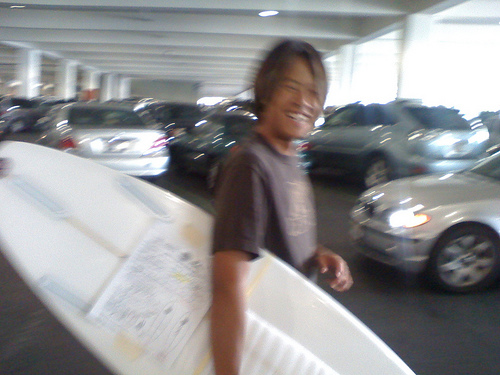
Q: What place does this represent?
A: It represents the garage.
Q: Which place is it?
A: It is a garage.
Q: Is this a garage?
A: Yes, it is a garage.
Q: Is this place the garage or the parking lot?
A: It is the garage.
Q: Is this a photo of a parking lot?
A: No, the picture is showing a garage.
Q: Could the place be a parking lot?
A: No, it is a garage.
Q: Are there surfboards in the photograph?
A: Yes, there is a surfboard.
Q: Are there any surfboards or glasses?
A: Yes, there is a surfboard.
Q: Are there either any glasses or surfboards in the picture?
A: Yes, there is a surfboard.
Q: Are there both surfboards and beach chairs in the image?
A: No, there is a surfboard but no beach chairs.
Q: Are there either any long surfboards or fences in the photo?
A: Yes, there is a long surfboard.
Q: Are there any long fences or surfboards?
A: Yes, there is a long surfboard.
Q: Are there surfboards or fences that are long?
A: Yes, the surfboard is long.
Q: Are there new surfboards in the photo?
A: Yes, there is a new surfboard.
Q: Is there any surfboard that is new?
A: Yes, there is a surfboard that is new.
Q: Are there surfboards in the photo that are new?
A: Yes, there is a surfboard that is new.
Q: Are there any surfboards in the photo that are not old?
A: Yes, there is an new surfboard.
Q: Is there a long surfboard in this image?
A: Yes, there is a long surfboard.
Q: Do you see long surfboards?
A: Yes, there is a long surfboard.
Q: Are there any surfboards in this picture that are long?
A: Yes, there is a surfboard that is long.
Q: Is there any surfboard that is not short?
A: Yes, there is a long surfboard.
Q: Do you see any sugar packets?
A: No, there are no sugar packets.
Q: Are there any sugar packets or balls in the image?
A: No, there are no sugar packets or balls.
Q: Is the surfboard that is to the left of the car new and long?
A: Yes, the surfboard is new and long.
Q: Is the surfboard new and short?
A: No, the surfboard is new but long.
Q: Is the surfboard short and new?
A: No, the surfboard is new but long.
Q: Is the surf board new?
A: Yes, the surf board is new.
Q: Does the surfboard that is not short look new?
A: Yes, the surfboard is new.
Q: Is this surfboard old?
A: No, the surfboard is new.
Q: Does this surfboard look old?
A: No, the surfboard is new.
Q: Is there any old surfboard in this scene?
A: No, there is a surfboard but it is new.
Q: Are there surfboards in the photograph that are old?
A: No, there is a surfboard but it is new.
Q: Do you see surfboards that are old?
A: No, there is a surfboard but it is new.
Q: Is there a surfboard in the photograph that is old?
A: No, there is a surfboard but it is new.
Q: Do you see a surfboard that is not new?
A: No, there is a surfboard but it is new.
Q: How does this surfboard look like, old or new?
A: The surfboard is new.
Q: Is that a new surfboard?
A: Yes, that is a new surfboard.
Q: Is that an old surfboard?
A: No, that is a new surfboard.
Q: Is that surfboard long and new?
A: Yes, the surfboard is long and new.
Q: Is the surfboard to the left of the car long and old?
A: No, the surfboard is long but new.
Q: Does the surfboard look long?
A: Yes, the surfboard is long.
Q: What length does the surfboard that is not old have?
A: The surfboard has long length.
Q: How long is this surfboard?
A: The surfboard is long.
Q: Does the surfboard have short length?
A: No, the surfboard is long.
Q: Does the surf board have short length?
A: No, the surf board is long.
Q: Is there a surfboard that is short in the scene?
A: No, there is a surfboard but it is long.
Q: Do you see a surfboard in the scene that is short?
A: No, there is a surfboard but it is long.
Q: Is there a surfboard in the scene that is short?
A: No, there is a surfboard but it is long.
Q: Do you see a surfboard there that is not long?
A: No, there is a surfboard but it is long.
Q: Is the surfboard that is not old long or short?
A: The surf board is long.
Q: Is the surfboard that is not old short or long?
A: The surf board is long.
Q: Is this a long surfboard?
A: Yes, this is a long surfboard.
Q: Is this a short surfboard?
A: No, this is a long surfboard.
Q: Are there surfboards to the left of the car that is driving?
A: Yes, there is a surfboard to the left of the car.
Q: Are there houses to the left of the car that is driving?
A: No, there is a surfboard to the left of the car.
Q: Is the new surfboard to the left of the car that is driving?
A: Yes, the surfboard is to the left of the car.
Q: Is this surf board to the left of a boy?
A: No, the surf board is to the left of the car.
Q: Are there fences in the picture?
A: No, there are no fences.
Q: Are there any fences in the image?
A: No, there are no fences.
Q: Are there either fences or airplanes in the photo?
A: No, there are no fences or airplanes.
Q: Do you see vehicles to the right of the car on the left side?
A: Yes, there is a vehicle to the right of the car.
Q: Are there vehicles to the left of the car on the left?
A: No, the vehicle is to the right of the car.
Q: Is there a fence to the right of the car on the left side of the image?
A: No, there is a vehicle to the right of the car.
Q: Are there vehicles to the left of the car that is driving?
A: Yes, there is a vehicle to the left of the car.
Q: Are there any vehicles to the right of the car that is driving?
A: No, the vehicle is to the left of the car.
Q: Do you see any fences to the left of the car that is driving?
A: No, there is a vehicle to the left of the car.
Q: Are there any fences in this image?
A: No, there are no fences.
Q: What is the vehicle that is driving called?
A: The vehicle is a car.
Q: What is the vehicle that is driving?
A: The vehicle is a car.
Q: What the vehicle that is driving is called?
A: The vehicle is a car.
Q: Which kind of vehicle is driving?
A: The vehicle is a car.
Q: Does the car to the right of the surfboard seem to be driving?
A: Yes, the car is driving.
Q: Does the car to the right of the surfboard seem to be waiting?
A: No, the car is driving.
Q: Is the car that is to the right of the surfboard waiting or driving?
A: The car is driving.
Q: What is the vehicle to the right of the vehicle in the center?
A: The vehicle is a car.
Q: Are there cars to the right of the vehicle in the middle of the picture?
A: Yes, there is a car to the right of the vehicle.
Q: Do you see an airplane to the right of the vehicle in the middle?
A: No, there is a car to the right of the vehicle.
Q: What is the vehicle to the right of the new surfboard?
A: The vehicle is a car.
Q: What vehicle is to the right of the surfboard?
A: The vehicle is a car.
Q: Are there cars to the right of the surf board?
A: Yes, there is a car to the right of the surf board.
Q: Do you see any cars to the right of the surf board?
A: Yes, there is a car to the right of the surf board.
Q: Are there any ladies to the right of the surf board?
A: No, there is a car to the right of the surf board.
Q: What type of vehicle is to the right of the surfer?
A: The vehicle is a car.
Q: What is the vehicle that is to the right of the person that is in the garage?
A: The vehicle is a car.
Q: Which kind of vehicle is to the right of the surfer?
A: The vehicle is a car.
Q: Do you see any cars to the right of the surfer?
A: Yes, there is a car to the right of the surfer.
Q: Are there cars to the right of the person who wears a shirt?
A: Yes, there is a car to the right of the surfer.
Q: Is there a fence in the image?
A: No, there are no fences.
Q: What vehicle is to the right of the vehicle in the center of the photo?
A: The vehicle is a car.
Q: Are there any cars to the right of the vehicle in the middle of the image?
A: Yes, there is a car to the right of the vehicle.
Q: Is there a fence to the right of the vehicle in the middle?
A: No, there is a car to the right of the vehicle.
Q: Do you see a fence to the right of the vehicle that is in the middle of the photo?
A: No, there is a car to the right of the vehicle.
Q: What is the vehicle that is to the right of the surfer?
A: The vehicle is a car.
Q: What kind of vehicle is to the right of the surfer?
A: The vehicle is a car.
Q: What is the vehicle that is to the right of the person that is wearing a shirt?
A: The vehicle is a car.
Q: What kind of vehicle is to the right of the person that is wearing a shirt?
A: The vehicle is a car.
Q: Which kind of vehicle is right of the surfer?
A: The vehicle is a car.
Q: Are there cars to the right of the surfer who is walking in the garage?
A: Yes, there is a car to the right of the surfer.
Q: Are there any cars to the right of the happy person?
A: Yes, there is a car to the right of the surfer.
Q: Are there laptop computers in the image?
A: No, there are no laptop computers.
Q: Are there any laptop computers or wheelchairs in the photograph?
A: No, there are no laptop computers or wheelchairs.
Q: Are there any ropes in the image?
A: No, there are no ropes.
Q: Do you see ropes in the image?
A: No, there are no ropes.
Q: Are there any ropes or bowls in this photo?
A: No, there are no ropes or bowls.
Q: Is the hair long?
A: Yes, the hair is long.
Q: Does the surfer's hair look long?
A: Yes, the hair is long.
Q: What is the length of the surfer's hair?
A: The hair is long.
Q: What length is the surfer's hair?
A: The hair is long.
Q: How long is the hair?
A: The hair is long.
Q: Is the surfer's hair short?
A: No, the hair is long.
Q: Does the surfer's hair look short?
A: No, the hair is long.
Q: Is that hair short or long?
A: The hair is long.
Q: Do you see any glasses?
A: No, there are no glasses.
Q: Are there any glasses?
A: No, there are no glasses.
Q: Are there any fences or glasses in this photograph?
A: No, there are no glasses or fences.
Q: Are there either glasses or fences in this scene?
A: No, there are no glasses or fences.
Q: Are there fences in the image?
A: No, there are no fences.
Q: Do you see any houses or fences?
A: No, there are no fences or houses.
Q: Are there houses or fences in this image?
A: No, there are no fences or houses.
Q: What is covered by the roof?
A: The garage is covered by the roof.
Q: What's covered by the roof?
A: The garage is covered by the roof.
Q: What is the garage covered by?
A: The garage is covered by the roof.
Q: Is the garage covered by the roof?
A: Yes, the garage is covered by the roof.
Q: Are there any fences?
A: No, there are no fences.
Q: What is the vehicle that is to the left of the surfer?
A: The vehicle is a car.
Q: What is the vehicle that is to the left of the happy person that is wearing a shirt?
A: The vehicle is a car.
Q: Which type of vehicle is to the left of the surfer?
A: The vehicle is a car.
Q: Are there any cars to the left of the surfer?
A: Yes, there is a car to the left of the surfer.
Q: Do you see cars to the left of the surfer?
A: Yes, there is a car to the left of the surfer.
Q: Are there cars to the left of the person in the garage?
A: Yes, there is a car to the left of the surfer.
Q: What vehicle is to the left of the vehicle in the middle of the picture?
A: The vehicle is a car.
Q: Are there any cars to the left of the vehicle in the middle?
A: Yes, there is a car to the left of the vehicle.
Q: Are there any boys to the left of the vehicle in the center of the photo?
A: No, there is a car to the left of the vehicle.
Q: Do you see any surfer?
A: Yes, there is a surfer.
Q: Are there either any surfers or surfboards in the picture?
A: Yes, there is a surfer.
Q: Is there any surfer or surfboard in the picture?
A: Yes, there is a surfer.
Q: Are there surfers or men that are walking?
A: Yes, the surfer is walking.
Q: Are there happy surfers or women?
A: Yes, there is a happy surfer.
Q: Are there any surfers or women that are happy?
A: Yes, the surfer is happy.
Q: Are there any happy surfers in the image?
A: Yes, there is a happy surfer.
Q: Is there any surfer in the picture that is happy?
A: Yes, there is a surfer that is happy.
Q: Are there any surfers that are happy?
A: Yes, there is a surfer that is happy.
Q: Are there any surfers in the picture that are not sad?
A: Yes, there is a happy surfer.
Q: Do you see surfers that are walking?
A: Yes, there is a surfer that is walking.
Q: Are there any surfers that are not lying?
A: Yes, there is a surfer that is walking.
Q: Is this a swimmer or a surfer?
A: This is a surfer.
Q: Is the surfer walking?
A: Yes, the surfer is walking.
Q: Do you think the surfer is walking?
A: Yes, the surfer is walking.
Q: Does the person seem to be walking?
A: Yes, the surfer is walking.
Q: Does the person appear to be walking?
A: Yes, the surfer is walking.